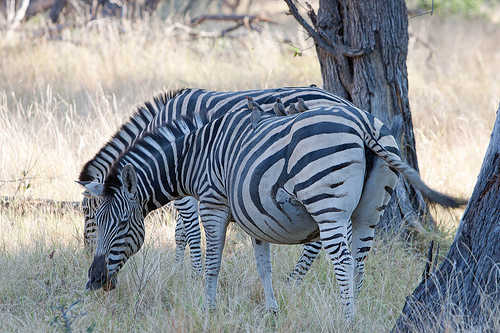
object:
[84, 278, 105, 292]
mouth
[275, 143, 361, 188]
stripes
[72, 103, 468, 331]
coat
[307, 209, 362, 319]
leg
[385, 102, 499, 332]
tree trunk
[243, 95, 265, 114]
birds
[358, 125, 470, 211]
tail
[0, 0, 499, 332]
grass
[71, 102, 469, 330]
zebra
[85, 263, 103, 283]
nose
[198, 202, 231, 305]
front leg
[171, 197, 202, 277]
front leg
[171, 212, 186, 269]
front leg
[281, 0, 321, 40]
branches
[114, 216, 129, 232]
eye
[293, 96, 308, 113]
birds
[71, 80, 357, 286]
zebras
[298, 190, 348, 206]
stripes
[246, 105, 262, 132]
birds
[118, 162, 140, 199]
ear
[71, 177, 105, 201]
ear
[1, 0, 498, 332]
field